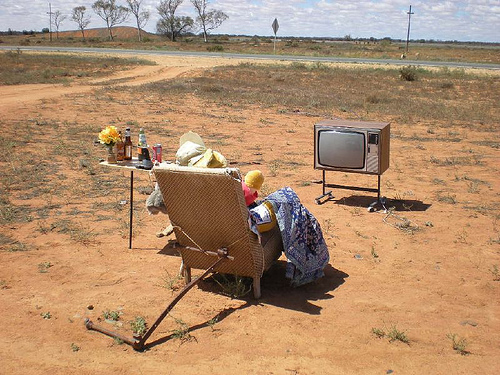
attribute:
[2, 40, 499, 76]
road — gray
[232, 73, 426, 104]
grass — parched, green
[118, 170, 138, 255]
leg — black, tall